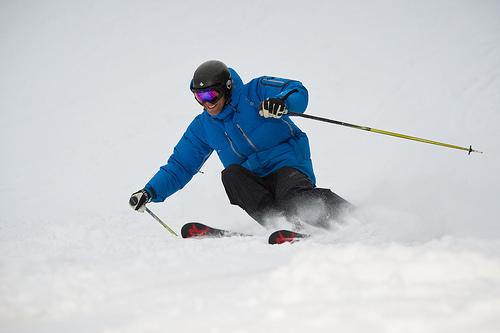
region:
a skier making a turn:
[130, 60, 365, 241]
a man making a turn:
[126, 60, 351, 241]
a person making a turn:
[128, 60, 356, 244]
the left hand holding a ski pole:
[261, 102, 483, 157]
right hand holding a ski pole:
[127, 192, 177, 236]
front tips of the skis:
[180, 217, 301, 245]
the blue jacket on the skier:
[145, 68, 315, 203]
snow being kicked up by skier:
[212, 196, 477, 248]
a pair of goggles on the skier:
[192, 80, 232, 105]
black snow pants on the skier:
[219, 166, 353, 229]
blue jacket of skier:
[146, 78, 315, 204]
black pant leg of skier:
[220, 164, 274, 236]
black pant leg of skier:
[266, 173, 359, 228]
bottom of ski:
[271, 230, 306, 247]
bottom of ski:
[183, 220, 254, 240]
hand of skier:
[129, 185, 154, 210]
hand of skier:
[258, 94, 292, 119]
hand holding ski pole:
[126, 187, 186, 242]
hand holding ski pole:
[255, 96, 482, 155]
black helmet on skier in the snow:
[192, 58, 229, 118]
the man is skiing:
[129, 62, 485, 244]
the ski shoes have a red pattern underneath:
[180, 220, 310, 247]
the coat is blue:
[142, 68, 315, 204]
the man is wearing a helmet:
[145, 62, 350, 249]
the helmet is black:
[188, 59, 235, 103]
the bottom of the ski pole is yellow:
[258, 108, 483, 153]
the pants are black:
[222, 159, 362, 235]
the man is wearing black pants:
[127, 59, 362, 238]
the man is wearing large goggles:
[146, 60, 369, 239]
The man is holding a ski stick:
[128, 184, 183, 244]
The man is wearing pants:
[221, 153, 378, 228]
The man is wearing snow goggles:
[189, 73, 233, 109]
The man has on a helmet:
[181, 54, 236, 105]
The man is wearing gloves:
[251, 91, 297, 123]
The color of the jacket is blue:
[172, 97, 314, 179]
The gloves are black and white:
[253, 95, 289, 126]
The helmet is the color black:
[187, 56, 232, 113]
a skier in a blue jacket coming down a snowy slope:
[3, 0, 498, 331]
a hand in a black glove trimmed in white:
[256, 91, 293, 122]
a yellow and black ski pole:
[287, 109, 487, 155]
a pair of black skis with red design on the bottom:
[178, 220, 341, 245]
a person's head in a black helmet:
[184, 57, 234, 118]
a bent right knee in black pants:
[216, 160, 260, 202]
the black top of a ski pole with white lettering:
[122, 193, 144, 208]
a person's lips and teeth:
[202, 101, 219, 110]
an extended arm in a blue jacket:
[148, 113, 206, 198]